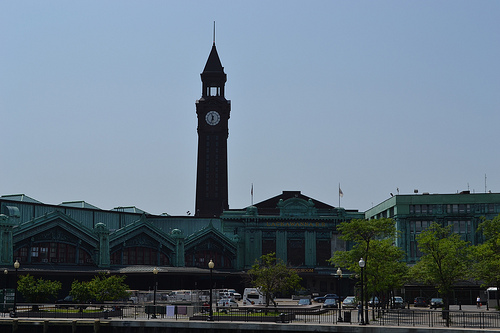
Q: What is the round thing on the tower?
A: A clock.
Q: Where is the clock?
A: On the tower.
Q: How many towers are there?
A: 1.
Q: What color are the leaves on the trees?
A: Green.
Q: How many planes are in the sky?
A: None.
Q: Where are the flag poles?
A: On the top of the main building.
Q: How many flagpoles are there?
A: 2.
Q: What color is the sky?
A: Light blue.